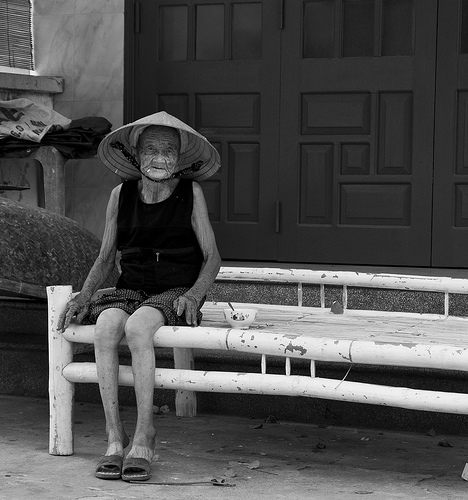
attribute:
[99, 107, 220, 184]
straw hat — large 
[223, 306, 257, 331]
bowl — small 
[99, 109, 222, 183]
hat — pointy, straw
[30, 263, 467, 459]
bench — bamboo, wooden, old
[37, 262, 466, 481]
bench — wooden , old 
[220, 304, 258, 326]
bowl — small 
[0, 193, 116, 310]
wicker basket — large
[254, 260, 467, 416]
bench — wooden 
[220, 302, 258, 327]
bowl — small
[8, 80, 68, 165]
newspaper — crumpled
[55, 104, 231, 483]
woman — thin, older, old 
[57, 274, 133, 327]
basket — large 